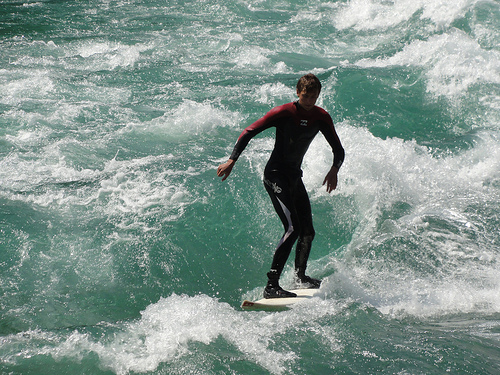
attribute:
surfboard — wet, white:
[241, 273, 328, 333]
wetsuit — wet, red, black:
[227, 107, 337, 285]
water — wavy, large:
[2, 2, 495, 369]